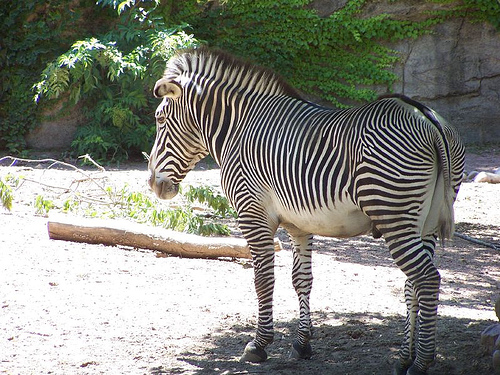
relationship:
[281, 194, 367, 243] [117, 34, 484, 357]
belly of zebra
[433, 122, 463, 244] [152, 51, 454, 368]
tail of zebra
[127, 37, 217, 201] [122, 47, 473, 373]
head of zebra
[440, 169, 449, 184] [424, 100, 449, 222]
edge of tail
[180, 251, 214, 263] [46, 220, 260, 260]
edge of log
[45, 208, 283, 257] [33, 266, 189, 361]
log laying on ground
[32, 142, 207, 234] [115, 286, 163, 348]
leafy branch laying on ground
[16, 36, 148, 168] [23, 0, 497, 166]
plant near wall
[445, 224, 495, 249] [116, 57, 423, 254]
stick near zebra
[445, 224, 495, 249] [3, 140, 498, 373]
stick laying on ground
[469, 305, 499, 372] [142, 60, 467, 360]
rocks near zebra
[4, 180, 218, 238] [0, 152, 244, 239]
leaves on tree limb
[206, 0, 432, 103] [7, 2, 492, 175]
vine growing on wall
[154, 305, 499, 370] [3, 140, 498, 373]
shadow on ground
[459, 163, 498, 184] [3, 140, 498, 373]
rocks on ground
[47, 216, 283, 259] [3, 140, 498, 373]
log on ground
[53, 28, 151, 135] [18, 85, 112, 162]
plant on rock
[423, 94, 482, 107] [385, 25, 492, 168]
crack in rock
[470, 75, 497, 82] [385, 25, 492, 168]
crack in rock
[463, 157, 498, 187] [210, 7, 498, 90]
rocks in background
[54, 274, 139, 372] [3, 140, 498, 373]
part of ground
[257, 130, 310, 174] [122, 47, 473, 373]
part of a zebra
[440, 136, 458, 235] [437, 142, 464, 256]
part of a tail